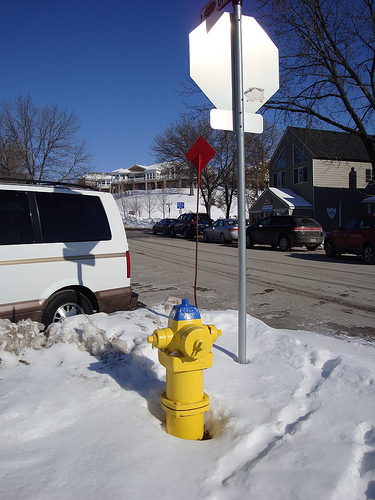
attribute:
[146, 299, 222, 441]
hydrant — yellow, fire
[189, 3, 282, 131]
traffic sign — red, viewed, stop sign, white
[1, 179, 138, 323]
van — parked, white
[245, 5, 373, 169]
tree — dry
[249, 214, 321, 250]
car — parked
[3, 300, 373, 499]
snow — white, dirty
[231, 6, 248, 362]
pole — metal